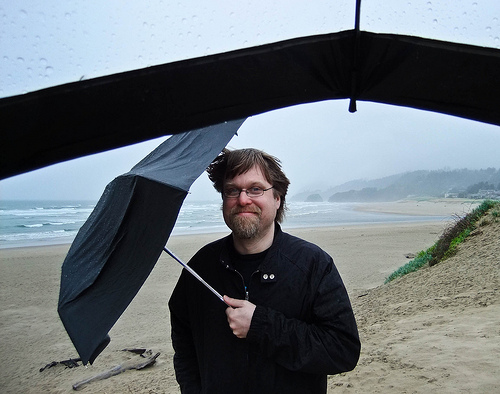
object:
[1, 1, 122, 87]
raining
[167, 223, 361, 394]
jacket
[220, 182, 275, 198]
glasses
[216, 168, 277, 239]
face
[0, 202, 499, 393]
sand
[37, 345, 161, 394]
wood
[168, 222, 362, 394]
black shirt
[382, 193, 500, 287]
plants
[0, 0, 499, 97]
drops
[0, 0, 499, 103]
part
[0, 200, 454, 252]
waves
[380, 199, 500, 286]
grass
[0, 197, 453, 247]
blue water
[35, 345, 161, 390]
driftwood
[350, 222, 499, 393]
footprints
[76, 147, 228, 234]
umbrella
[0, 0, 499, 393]
area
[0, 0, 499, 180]
open window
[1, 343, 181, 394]
footprints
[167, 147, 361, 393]
man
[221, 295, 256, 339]
hand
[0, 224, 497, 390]
beach